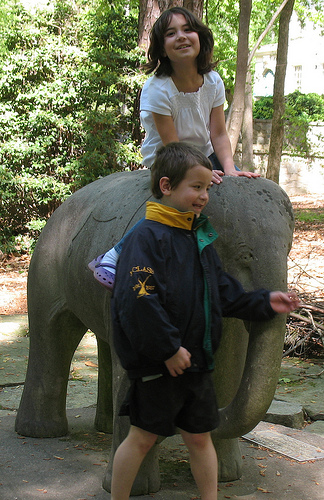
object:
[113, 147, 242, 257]
pants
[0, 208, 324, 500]
ground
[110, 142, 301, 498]
child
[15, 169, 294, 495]
elephant statue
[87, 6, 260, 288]
girl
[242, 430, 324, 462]
plaque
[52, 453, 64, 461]
leaf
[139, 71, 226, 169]
shirt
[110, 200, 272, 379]
jacket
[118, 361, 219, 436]
shorts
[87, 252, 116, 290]
shoe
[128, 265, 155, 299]
logo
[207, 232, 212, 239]
button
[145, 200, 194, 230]
collar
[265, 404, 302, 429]
stone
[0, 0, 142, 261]
tree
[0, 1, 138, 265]
tree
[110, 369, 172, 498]
leg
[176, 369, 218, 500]
leg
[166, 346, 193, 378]
hand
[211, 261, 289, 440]
trunk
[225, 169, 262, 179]
hand